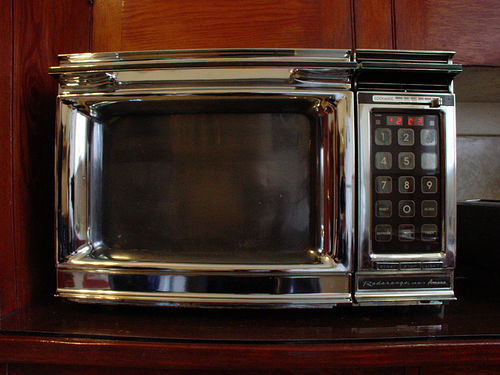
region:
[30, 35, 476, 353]
silver microwave below cabinets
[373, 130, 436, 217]
white numbers on buttons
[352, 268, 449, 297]
words on front of microwave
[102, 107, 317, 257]
window on front of microwave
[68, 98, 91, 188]
light reflection on microwave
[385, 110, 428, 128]
red numbers on digital display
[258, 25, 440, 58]
wood cabinets above microwave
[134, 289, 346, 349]
flat glass under microwave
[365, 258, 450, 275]
three buttons on microwave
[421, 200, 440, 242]
words on square buttons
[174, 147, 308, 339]
the microwave is silver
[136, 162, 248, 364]
the microwave is silver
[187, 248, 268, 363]
the microwave is silver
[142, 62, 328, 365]
the microwave is silver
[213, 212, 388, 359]
the microwave is silver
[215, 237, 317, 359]
the microwave is silver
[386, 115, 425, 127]
Digital timer with red letters.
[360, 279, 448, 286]
Microwave brand name in silver.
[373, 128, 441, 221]
Number key pad on microwave.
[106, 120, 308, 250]
Mircowave see through door.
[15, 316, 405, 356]
Brown cabinet shelf topped with glass.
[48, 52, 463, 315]
Silver and black microwave on shelf.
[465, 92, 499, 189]
Wall in back of microwave.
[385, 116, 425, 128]
Digital timer showing 2 mins and 2 seconds.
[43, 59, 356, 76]
Silver and black ledge on microwave.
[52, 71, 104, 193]
Light reflecting off the microwave.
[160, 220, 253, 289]
the microwave is silver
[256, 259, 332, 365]
the microwave is silver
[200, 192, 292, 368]
the microwave is silver